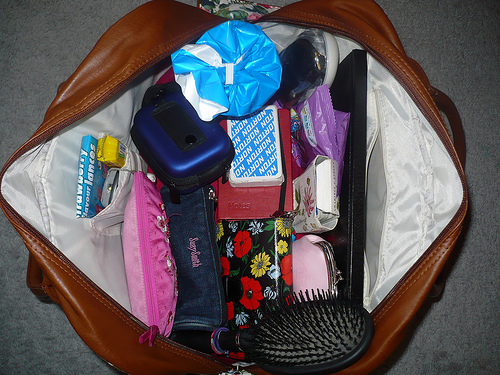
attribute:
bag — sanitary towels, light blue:
[151, 28, 308, 109]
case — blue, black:
[142, 81, 224, 192]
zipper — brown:
[358, 27, 472, 345]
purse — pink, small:
[147, 112, 219, 179]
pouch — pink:
[120, 167, 180, 345]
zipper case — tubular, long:
[158, 185, 234, 352]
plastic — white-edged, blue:
[169, 20, 283, 124]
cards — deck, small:
[224, 104, 284, 189]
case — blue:
[133, 103, 231, 185]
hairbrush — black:
[153, 285, 406, 373]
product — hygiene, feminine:
[297, 82, 353, 160]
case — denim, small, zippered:
[157, 178, 231, 335]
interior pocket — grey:
[76, 135, 146, 233]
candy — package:
[91, 133, 140, 172]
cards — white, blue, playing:
[213, 90, 291, 187]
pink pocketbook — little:
[290, 232, 341, 294]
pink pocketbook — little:
[221, 177, 300, 219]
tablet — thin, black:
[324, 47, 379, 324]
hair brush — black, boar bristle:
[194, 283, 379, 373]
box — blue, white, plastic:
[227, 95, 282, 187]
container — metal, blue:
[138, 87, 236, 194]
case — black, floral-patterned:
[193, 217, 302, 341]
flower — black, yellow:
[251, 252, 273, 276]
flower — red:
[231, 229, 251, 256]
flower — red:
[237, 276, 264, 306]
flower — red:
[221, 255, 229, 274]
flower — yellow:
[274, 236, 288, 255]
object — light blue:
[169, 19, 286, 123]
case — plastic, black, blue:
[124, 90, 243, 198]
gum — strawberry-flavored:
[76, 139, 104, 221]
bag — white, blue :
[169, 17, 276, 118]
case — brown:
[9, 5, 472, 365]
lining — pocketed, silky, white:
[337, 53, 457, 305]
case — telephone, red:
[224, 111, 294, 216]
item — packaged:
[168, 15, 287, 124]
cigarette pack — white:
[281, 156, 342, 239]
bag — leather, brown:
[7, 4, 475, 372]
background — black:
[221, 209, 285, 325]